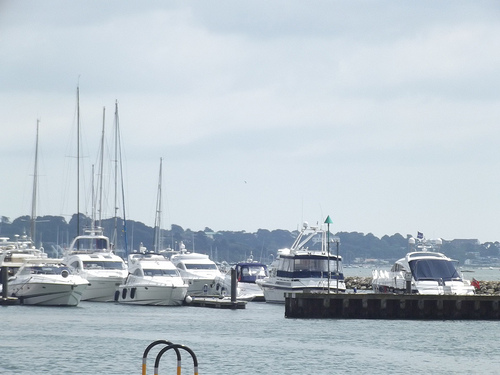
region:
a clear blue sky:
[214, 44, 408, 152]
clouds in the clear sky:
[240, 20, 496, 132]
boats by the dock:
[55, 216, 257, 311]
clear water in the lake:
[204, 326, 382, 373]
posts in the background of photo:
[40, 92, 166, 241]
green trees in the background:
[181, 213, 296, 263]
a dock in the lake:
[266, 278, 498, 345]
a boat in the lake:
[158, 228, 245, 329]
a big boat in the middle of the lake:
[252, 205, 355, 310]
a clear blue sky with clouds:
[198, 86, 351, 193]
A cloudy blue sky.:
[195, 35, 487, 207]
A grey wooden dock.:
[282, 292, 498, 316]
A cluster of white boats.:
[0, 73, 244, 306]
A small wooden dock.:
[200, 265, 247, 308]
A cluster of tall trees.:
[214, 227, 278, 259]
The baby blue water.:
[236, 320, 407, 374]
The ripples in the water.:
[245, 353, 270, 373]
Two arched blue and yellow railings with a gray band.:
[141, 338, 201, 373]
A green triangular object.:
[321, 215, 338, 225]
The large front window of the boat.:
[410, 260, 462, 279]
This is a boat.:
[371, 236, 461, 301]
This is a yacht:
[243, 230, 346, 318]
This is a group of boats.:
[18, 220, 224, 320]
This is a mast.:
[61, 81, 93, 239]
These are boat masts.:
[20, 93, 188, 246]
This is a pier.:
[281, 277, 497, 337]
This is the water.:
[11, 307, 485, 373]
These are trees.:
[6, 200, 498, 282]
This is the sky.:
[3, 75, 490, 232]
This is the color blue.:
[223, 312, 272, 359]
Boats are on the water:
[23, 183, 445, 357]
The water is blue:
[86, 315, 379, 358]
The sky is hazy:
[111, 79, 463, 336]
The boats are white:
[23, 224, 242, 336]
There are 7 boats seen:
[23, 232, 497, 334]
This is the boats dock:
[276, 275, 490, 347]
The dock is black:
[280, 272, 487, 339]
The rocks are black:
[101, 212, 456, 258]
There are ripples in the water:
[141, 327, 447, 369]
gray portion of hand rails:
[135, 338, 205, 359]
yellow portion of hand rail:
[129, 367, 160, 374]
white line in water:
[176, 329, 372, 356]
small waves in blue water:
[37, 346, 82, 366]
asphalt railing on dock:
[307, 291, 372, 305]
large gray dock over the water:
[277, 287, 489, 331]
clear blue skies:
[217, 137, 407, 188]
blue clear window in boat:
[401, 257, 466, 278]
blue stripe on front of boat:
[10, 290, 87, 310]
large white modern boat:
[400, 225, 471, 300]